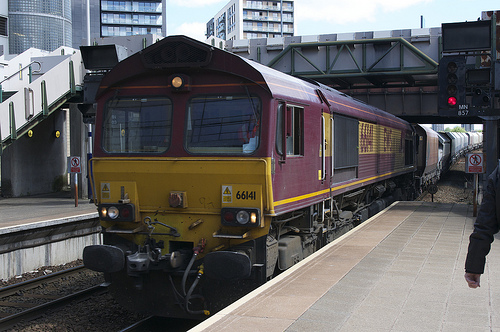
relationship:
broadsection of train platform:
[260, 149, 402, 299] [181, 199, 498, 330]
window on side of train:
[274, 104, 305, 161] [77, 34, 428, 317]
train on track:
[76, 3, 481, 315] [11, 263, 147, 330]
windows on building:
[82, 0, 165, 36] [0, 0, 167, 54]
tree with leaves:
[441, 125, 468, 134] [439, 121, 467, 133]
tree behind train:
[441, 125, 468, 134] [76, 3, 481, 315]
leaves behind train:
[439, 121, 467, 133] [76, 3, 481, 315]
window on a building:
[23, 17, 26, 20] [0, 0, 72, 53]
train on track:
[76, 3, 481, 315] [33, 221, 197, 326]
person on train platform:
[459, 149, 499, 288] [181, 199, 498, 330]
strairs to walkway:
[10, 52, 47, 114] [41, 27, 129, 77]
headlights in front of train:
[93, 192, 269, 230] [80, 30, 460, 273]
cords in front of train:
[162, 237, 223, 322] [76, 3, 481, 315]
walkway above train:
[216, 20, 488, 79] [80, 30, 460, 273]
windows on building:
[106, 7, 146, 36] [97, 1, 175, 47]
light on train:
[169, 75, 184, 87] [76, 3, 481, 315]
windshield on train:
[163, 83, 268, 172] [68, 28, 498, 303]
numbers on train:
[234, 188, 258, 203] [76, 3, 481, 315]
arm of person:
[463, 134, 481, 232] [442, 139, 490, 267]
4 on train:
[247, 190, 259, 199] [85, 35, 480, 293]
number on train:
[234, 193, 241, 199] [85, 35, 480, 293]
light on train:
[75, 176, 297, 248] [68, 3, 453, 295]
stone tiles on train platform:
[373, 265, 448, 317] [181, 199, 498, 330]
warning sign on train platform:
[462, 145, 487, 176] [181, 199, 498, 330]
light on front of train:
[98, 205, 108, 218] [76, 3, 481, 315]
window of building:
[103, 10, 115, 22] [70, 0, 169, 56]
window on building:
[109, 12, 120, 22] [68, 0, 163, 46]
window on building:
[102, 12, 132, 26] [98, 1, 167, 42]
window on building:
[103, 10, 115, 22] [15, 3, 391, 154]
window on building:
[245, 31, 267, 38] [203, 0, 298, 39]